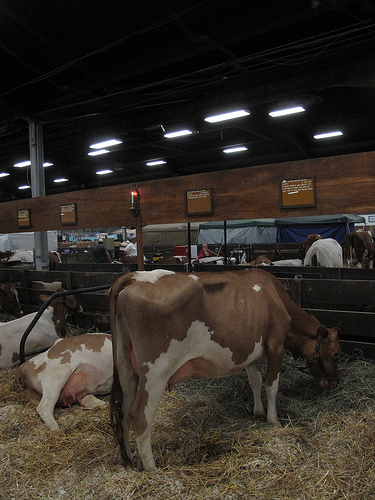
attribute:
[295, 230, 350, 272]
cow — standing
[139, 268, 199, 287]
spot — white 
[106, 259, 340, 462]
cow — eating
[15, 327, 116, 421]
cow — white, brown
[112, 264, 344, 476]
cow — standing